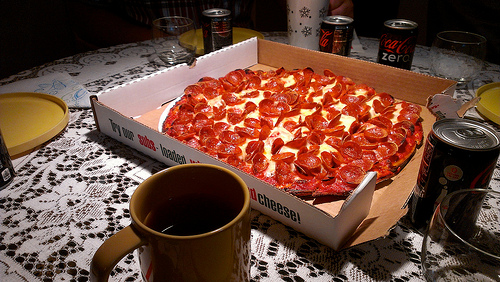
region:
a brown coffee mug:
[80, 158, 255, 280]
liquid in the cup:
[140, 185, 241, 236]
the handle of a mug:
[81, 224, 141, 280]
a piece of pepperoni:
[268, 145, 297, 163]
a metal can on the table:
[401, 114, 496, 241]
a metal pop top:
[452, 120, 487, 142]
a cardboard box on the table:
[86, 31, 486, 251]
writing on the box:
[105, 115, 305, 228]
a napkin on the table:
[0, 60, 101, 111]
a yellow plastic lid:
[0, 86, 72, 163]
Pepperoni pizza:
[155, 56, 422, 201]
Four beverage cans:
[197, 3, 499, 225]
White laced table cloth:
[27, 153, 103, 256]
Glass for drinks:
[148, 12, 198, 65]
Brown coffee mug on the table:
[83, 166, 280, 280]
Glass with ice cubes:
[426, 31, 490, 86]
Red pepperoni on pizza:
[197, 78, 376, 160]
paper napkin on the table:
[1, 68, 96, 110]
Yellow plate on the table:
[0, 90, 68, 156]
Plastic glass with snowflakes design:
[285, 0, 325, 47]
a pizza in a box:
[128, 84, 432, 204]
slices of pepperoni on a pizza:
[203, 100, 315, 140]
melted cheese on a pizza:
[301, 94, 366, 158]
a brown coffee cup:
[89, 173, 262, 280]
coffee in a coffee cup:
[117, 178, 257, 257]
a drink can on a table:
[372, 22, 420, 72]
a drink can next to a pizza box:
[304, 11, 361, 76]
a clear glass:
[153, 16, 195, 73]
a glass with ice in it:
[423, 20, 490, 83]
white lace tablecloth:
[6, 162, 116, 280]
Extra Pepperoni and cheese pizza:
[156, 62, 426, 188]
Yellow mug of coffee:
[85, 160, 250, 275]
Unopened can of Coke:
[405, 115, 495, 240]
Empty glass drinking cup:
[145, 10, 195, 60]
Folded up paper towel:
[10, 65, 100, 105]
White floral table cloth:
[0, 25, 495, 270]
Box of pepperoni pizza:
[85, 30, 465, 250]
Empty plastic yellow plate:
[0, 85, 75, 155]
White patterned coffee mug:
[280, 0, 335, 50]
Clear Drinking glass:
[430, 26, 487, 82]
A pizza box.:
[91, 35, 461, 254]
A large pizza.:
[164, 62, 426, 192]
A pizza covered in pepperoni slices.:
[159, 59, 424, 187]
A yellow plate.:
[2, 90, 71, 155]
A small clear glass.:
[156, 14, 198, 62]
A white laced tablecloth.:
[1, 31, 498, 280]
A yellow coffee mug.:
[89, 162, 250, 279]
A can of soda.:
[416, 119, 498, 245]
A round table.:
[0, 22, 497, 279]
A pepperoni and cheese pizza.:
[162, 62, 427, 197]